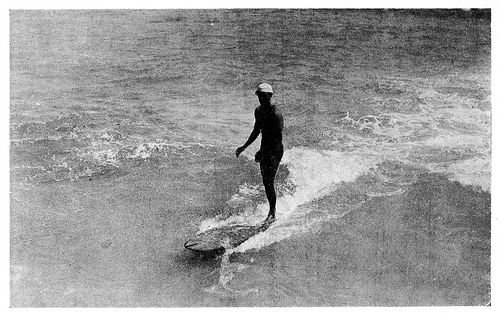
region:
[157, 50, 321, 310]
person on the surfboard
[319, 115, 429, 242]
the water is wavy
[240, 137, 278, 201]
person is wearing swim gear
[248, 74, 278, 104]
person is wearing swimming cap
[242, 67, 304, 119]
cap on the surfer's head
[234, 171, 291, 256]
feet on the surfboard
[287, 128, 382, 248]
wave in the water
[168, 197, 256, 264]
the surfboard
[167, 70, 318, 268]
man on a surfboard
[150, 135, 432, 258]
wave the man is riding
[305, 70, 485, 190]
foam from crashing waves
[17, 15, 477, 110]
ripples in the water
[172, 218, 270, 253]
old-fashioned surfboard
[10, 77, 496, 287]
man surfing in shallow waters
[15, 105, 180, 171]
splashing from the crashing wave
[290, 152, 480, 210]
wave cresting and about to crash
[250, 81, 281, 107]
man is wearing a hat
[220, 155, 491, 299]
waves make a triangle shape at right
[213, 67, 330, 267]
This is a person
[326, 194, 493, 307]
Section of a lake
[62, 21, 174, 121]
Section of a lake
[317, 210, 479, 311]
Section of a lake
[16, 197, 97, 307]
Section of a lake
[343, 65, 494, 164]
Section of a lake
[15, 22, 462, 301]
this is an older photo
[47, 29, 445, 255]
this is monochromatic style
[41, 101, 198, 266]
this is the ocean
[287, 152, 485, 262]
these are waves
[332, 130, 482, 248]
the waves are small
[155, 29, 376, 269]
the man is surfing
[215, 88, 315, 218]
the man has dark skin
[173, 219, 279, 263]
this is a surf board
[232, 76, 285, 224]
man on surf board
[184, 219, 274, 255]
long wooden brown surfboard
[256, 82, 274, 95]
small round white cap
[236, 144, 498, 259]
large rising white wave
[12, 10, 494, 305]
large open body of water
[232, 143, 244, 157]
small slender dark hand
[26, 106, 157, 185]
ripples in open water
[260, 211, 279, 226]
wide small white foot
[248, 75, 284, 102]
man wearing a white cap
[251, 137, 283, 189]
man wearing black shorts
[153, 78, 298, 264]
man on the surfboard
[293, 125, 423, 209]
waves crashing in the ocean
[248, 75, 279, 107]
man wearing a white cap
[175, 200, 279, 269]
black surfboard in the water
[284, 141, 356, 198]
white foam forming from waves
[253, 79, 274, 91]
man with a white cap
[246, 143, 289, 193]
man wearing black shorts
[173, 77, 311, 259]
man on a surfboard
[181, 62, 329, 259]
Old picture of a man on a wave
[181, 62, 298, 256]
Old picture of a man on a surfboard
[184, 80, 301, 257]
Man with a cap on a surfboard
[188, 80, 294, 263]
Man with a cap riding a wave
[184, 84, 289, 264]
Man in dark clothing on a surfboard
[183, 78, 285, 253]
Man in dark clothing riding a wave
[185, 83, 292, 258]
Man riding a small wave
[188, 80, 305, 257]
Old picture of man riding a surfboard on a little wave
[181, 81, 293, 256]
Man with a white cap and a black tank top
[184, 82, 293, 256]
Old picture with a dark colored man on a surfboard